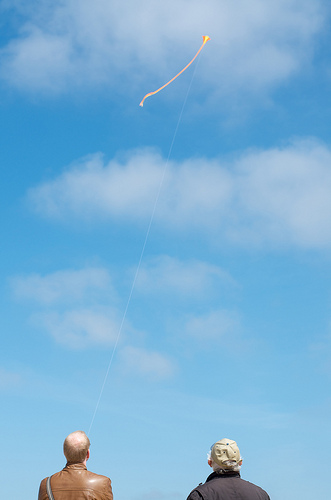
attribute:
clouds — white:
[2, 2, 328, 469]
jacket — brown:
[37, 460, 113, 498]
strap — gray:
[45, 474, 56, 499]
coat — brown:
[38, 467, 129, 498]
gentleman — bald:
[35, 429, 113, 498]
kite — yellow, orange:
[99, 32, 329, 135]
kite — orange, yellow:
[138, 33, 210, 106]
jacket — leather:
[19, 407, 115, 498]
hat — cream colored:
[208, 436, 242, 470]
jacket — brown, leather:
[36, 464, 123, 498]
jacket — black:
[184, 469, 269, 498]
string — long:
[84, 50, 215, 433]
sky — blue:
[0, 0, 331, 498]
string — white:
[114, 79, 207, 237]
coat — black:
[185, 471, 268, 498]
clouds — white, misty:
[30, 138, 320, 256]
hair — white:
[213, 466, 241, 471]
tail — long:
[141, 39, 210, 105]